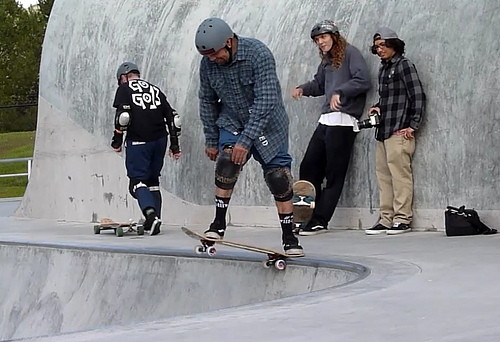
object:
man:
[367, 27, 426, 235]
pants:
[299, 122, 358, 224]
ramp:
[0, 244, 358, 338]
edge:
[0, 241, 371, 316]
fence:
[0, 157, 33, 182]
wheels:
[194, 245, 208, 255]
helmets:
[196, 18, 234, 55]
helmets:
[311, 21, 342, 38]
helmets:
[117, 62, 138, 82]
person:
[112, 63, 180, 234]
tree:
[0, 0, 54, 102]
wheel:
[274, 259, 287, 270]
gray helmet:
[193, 13, 234, 57]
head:
[195, 17, 234, 62]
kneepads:
[264, 167, 291, 199]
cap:
[372, 28, 400, 38]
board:
[178, 224, 292, 269]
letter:
[128, 79, 163, 110]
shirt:
[372, 54, 426, 141]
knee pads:
[215, 152, 242, 189]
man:
[289, 20, 370, 236]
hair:
[371, 39, 407, 58]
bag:
[443, 204, 496, 236]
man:
[194, 16, 305, 257]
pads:
[126, 179, 151, 199]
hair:
[320, 31, 355, 69]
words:
[128, 79, 162, 109]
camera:
[357, 113, 380, 129]